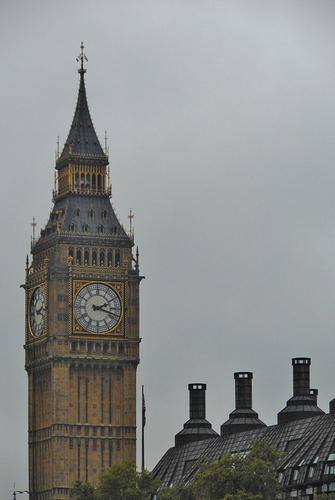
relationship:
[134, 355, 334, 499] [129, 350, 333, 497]
roof of building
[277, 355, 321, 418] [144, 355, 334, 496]
chimney on tower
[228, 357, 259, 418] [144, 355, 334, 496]
chimney on tower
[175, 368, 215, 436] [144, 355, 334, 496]
chimney on tower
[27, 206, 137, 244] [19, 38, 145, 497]
crosses on tower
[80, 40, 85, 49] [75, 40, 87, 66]
balls on top pole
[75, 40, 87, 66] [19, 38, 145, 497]
pole on tower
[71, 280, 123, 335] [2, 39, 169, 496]
clock on side tower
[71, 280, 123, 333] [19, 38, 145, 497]
clock on tower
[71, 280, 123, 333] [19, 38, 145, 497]
clock on a tower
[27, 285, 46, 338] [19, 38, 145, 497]
clock on a tower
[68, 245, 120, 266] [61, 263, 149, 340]
arches on a clock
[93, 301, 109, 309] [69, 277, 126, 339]
hand on a clock